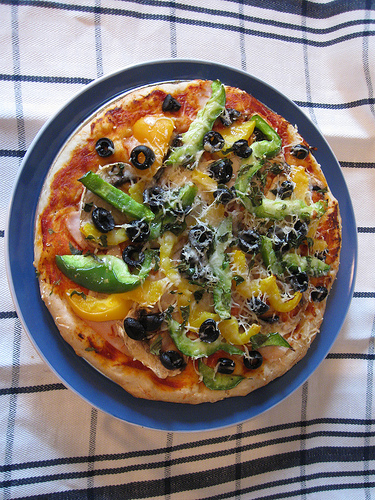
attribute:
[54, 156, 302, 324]
cheese — melted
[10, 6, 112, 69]
napkin — squared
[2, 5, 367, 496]
stripes — blue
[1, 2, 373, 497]
tablecloth — white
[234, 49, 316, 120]
dish — blue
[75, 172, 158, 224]
pepper — green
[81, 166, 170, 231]
pepper slice — green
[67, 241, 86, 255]
fresh basil — sprinkled 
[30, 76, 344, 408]
pizza — brown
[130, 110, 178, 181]
pepper — yellow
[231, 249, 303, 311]
pepper — yellow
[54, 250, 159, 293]
pepper — yellow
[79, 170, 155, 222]
pepper — yellow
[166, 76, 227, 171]
pepper — yellow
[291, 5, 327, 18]
lines — striped, blue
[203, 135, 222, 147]
olives — black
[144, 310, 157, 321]
olives — black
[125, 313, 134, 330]
olives — black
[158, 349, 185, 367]
olives — black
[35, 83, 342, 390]
sauce — tomato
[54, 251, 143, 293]
pepper — green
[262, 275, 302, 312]
yellow pepper — sliced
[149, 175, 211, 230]
cheese — Mozzarella, melted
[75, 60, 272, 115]
exterior — blue, plate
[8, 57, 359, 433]
plate — blue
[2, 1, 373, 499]
cloth — plaid, white, blue 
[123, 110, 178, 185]
pepper — yellow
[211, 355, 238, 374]
olive — black, sliced